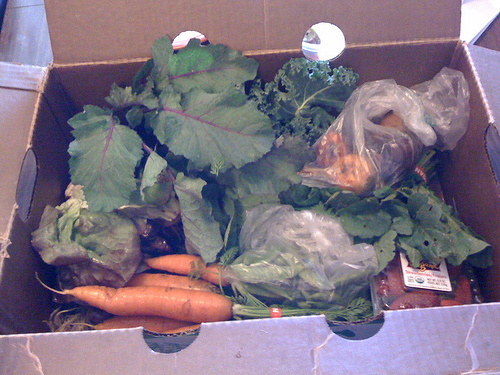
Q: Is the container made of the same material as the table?
A: No, the container is made of plastic and the table is made of wood.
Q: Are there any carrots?
A: Yes, there are carrots.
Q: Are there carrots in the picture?
A: Yes, there are carrots.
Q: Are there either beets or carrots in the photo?
A: Yes, there are carrots.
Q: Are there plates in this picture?
A: No, there are no plates.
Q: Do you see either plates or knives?
A: No, there are no plates or knives.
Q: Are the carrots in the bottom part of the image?
A: Yes, the carrots are in the bottom of the image.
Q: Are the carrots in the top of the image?
A: No, the carrots are in the bottom of the image.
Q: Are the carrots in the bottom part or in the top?
A: The carrots are in the bottom of the image.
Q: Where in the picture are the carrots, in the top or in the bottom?
A: The carrots are in the bottom of the image.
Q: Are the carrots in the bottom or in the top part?
A: The carrots are in the bottom of the image.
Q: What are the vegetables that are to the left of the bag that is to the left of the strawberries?
A: The vegetables are carrots.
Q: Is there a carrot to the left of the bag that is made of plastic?
A: Yes, there are carrots to the left of the bag.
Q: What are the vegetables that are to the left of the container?
A: The vegetables are carrots.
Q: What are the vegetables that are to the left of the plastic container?
A: The vegetables are carrots.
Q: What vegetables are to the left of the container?
A: The vegetables are carrots.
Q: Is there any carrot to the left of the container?
A: Yes, there are carrots to the left of the container.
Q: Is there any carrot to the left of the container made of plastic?
A: Yes, there are carrots to the left of the container.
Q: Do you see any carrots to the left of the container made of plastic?
A: Yes, there are carrots to the left of the container.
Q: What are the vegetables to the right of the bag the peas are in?
A: The vegetables are carrots.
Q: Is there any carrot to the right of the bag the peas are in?
A: Yes, there are carrots to the right of the bag.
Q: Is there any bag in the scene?
A: Yes, there is a bag.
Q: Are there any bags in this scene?
A: Yes, there is a bag.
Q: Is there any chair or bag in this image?
A: Yes, there is a bag.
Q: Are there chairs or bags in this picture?
A: Yes, there is a bag.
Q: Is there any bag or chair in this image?
A: Yes, there is a bag.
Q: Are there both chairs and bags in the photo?
A: No, there is a bag but no chairs.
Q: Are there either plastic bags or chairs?
A: Yes, there is a plastic bag.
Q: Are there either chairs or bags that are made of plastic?
A: Yes, the bag is made of plastic.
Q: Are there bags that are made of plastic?
A: Yes, there is a bag that is made of plastic.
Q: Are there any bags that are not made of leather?
A: Yes, there is a bag that is made of plastic.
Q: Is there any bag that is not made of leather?
A: Yes, there is a bag that is made of plastic.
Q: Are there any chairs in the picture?
A: No, there are no chairs.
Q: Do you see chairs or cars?
A: No, there are no chairs or cars.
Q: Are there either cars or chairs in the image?
A: No, there are no chairs or cars.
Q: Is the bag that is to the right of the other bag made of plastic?
A: Yes, the bag is made of plastic.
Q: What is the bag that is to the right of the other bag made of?
A: The bag is made of plastic.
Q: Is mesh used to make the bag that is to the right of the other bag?
A: No, the bag is made of plastic.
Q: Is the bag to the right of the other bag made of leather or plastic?
A: The bag is made of plastic.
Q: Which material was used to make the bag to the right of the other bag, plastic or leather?
A: The bag is made of plastic.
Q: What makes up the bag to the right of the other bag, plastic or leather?
A: The bag is made of plastic.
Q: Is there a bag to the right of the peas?
A: Yes, there is a bag to the right of the peas.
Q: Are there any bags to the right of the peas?
A: Yes, there is a bag to the right of the peas.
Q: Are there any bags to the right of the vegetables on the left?
A: Yes, there is a bag to the right of the peas.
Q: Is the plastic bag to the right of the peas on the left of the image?
A: Yes, the bag is to the right of the peas.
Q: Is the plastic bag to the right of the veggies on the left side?
A: Yes, the bag is to the right of the peas.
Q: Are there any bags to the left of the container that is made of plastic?
A: Yes, there is a bag to the left of the container.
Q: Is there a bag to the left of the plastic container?
A: Yes, there is a bag to the left of the container.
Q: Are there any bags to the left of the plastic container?
A: Yes, there is a bag to the left of the container.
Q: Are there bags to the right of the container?
A: No, the bag is to the left of the container.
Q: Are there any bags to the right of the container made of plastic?
A: No, the bag is to the left of the container.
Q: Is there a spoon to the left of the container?
A: No, there is a bag to the left of the container.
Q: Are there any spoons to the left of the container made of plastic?
A: No, there is a bag to the left of the container.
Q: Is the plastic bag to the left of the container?
A: Yes, the bag is to the left of the container.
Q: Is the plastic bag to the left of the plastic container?
A: Yes, the bag is to the left of the container.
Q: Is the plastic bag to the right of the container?
A: No, the bag is to the left of the container.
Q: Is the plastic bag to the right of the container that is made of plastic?
A: No, the bag is to the left of the container.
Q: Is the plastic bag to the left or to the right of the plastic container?
A: The bag is to the left of the container.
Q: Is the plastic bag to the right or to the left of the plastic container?
A: The bag is to the left of the container.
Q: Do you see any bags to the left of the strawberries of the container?
A: Yes, there is a bag to the left of the strawberries.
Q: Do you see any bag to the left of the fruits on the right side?
A: Yes, there is a bag to the left of the strawberries.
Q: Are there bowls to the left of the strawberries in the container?
A: No, there is a bag to the left of the strawberries.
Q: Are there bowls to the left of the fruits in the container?
A: No, there is a bag to the left of the strawberries.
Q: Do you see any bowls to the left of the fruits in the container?
A: No, there is a bag to the left of the strawberries.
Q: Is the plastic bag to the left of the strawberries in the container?
A: Yes, the bag is to the left of the strawberries.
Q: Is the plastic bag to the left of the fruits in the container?
A: Yes, the bag is to the left of the strawberries.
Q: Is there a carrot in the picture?
A: Yes, there is a carrot.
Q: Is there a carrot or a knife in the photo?
A: Yes, there is a carrot.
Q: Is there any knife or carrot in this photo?
A: Yes, there is a carrot.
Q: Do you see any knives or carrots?
A: Yes, there is a carrot.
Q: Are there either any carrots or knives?
A: Yes, there is a carrot.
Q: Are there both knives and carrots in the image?
A: No, there is a carrot but no knives.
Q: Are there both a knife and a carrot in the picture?
A: No, there is a carrot but no knives.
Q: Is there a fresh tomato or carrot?
A: Yes, there is a fresh carrot.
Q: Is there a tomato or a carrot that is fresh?
A: Yes, the carrot is fresh.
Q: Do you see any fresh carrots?
A: Yes, there is a fresh carrot.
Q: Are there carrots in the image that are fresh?
A: Yes, there is a carrot that is fresh.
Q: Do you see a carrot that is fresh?
A: Yes, there is a carrot that is fresh.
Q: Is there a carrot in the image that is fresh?
A: Yes, there is a carrot that is fresh.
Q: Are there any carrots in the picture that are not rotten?
A: Yes, there is a fresh carrot.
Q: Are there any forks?
A: No, there are no forks.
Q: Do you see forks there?
A: No, there are no forks.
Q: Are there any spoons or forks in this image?
A: No, there are no forks or spoons.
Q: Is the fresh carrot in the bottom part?
A: Yes, the carrot is in the bottom of the image.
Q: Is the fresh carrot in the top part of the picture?
A: No, the carrot is in the bottom of the image.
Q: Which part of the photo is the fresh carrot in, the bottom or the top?
A: The carrot is in the bottom of the image.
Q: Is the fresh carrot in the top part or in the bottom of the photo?
A: The carrot is in the bottom of the image.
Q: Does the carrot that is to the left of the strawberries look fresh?
A: Yes, the carrot is fresh.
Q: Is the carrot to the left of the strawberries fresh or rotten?
A: The carrot is fresh.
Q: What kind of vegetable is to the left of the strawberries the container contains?
A: The vegetable is a carrot.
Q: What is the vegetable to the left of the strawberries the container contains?
A: The vegetable is a carrot.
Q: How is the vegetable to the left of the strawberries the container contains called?
A: The vegetable is a carrot.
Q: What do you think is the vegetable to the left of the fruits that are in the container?
A: The vegetable is a carrot.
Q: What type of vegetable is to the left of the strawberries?
A: The vegetable is a carrot.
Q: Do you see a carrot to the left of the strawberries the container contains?
A: Yes, there is a carrot to the left of the strawberries.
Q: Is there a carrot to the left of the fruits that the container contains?
A: Yes, there is a carrot to the left of the strawberries.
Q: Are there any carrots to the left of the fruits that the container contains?
A: Yes, there is a carrot to the left of the strawberries.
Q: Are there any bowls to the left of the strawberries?
A: No, there is a carrot to the left of the strawberries.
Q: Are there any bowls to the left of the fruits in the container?
A: No, there is a carrot to the left of the strawberries.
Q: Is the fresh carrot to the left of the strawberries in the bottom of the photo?
A: Yes, the carrot is to the left of the strawberries.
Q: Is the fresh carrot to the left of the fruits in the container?
A: Yes, the carrot is to the left of the strawberries.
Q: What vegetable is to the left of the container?
A: The vegetable is a carrot.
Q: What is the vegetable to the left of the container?
A: The vegetable is a carrot.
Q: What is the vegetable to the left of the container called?
A: The vegetable is a carrot.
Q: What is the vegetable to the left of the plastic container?
A: The vegetable is a carrot.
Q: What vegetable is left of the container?
A: The vegetable is a carrot.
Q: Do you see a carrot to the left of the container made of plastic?
A: Yes, there is a carrot to the left of the container.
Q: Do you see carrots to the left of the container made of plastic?
A: Yes, there is a carrot to the left of the container.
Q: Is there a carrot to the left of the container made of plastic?
A: Yes, there is a carrot to the left of the container.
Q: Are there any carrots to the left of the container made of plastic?
A: Yes, there is a carrot to the left of the container.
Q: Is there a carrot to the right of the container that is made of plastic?
A: No, the carrot is to the left of the container.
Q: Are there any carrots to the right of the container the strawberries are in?
A: No, the carrot is to the left of the container.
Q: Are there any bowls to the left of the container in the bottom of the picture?
A: No, there is a carrot to the left of the container.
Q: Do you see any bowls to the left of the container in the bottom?
A: No, there is a carrot to the left of the container.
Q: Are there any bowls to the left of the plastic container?
A: No, there is a carrot to the left of the container.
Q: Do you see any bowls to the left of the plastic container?
A: No, there is a carrot to the left of the container.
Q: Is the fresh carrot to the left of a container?
A: Yes, the carrot is to the left of a container.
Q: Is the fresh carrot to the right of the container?
A: No, the carrot is to the left of the container.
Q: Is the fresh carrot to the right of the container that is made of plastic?
A: No, the carrot is to the left of the container.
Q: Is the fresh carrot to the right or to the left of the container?
A: The carrot is to the left of the container.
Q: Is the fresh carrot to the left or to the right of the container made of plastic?
A: The carrot is to the left of the container.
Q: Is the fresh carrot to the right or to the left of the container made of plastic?
A: The carrot is to the left of the container.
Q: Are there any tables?
A: Yes, there is a table.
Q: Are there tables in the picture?
A: Yes, there is a table.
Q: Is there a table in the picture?
A: Yes, there is a table.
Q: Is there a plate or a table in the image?
A: Yes, there is a table.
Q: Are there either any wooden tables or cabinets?
A: Yes, there is a wood table.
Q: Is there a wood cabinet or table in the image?
A: Yes, there is a wood table.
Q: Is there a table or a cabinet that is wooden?
A: Yes, the table is wooden.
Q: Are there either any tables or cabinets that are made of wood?
A: Yes, the table is made of wood.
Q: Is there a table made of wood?
A: Yes, there is a table that is made of wood.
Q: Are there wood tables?
A: Yes, there is a table that is made of wood.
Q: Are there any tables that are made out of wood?
A: Yes, there is a table that is made of wood.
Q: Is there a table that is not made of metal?
A: Yes, there is a table that is made of wood.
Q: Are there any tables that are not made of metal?
A: Yes, there is a table that is made of wood.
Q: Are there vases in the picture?
A: No, there are no vases.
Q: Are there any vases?
A: No, there are no vases.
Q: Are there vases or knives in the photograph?
A: No, there are no vases or knives.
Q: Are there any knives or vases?
A: No, there are no vases or knives.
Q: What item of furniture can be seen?
A: The piece of furniture is a table.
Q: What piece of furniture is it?
A: The piece of furniture is a table.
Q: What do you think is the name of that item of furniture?
A: This is a table.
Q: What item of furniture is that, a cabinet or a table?
A: This is a table.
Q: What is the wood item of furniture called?
A: The piece of furniture is a table.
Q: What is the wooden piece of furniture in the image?
A: The piece of furniture is a table.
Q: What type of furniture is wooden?
A: The furniture is a table.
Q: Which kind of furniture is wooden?
A: The furniture is a table.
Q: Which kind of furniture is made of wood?
A: The furniture is a table.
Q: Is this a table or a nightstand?
A: This is a table.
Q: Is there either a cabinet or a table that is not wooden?
A: No, there is a table but it is wooden.